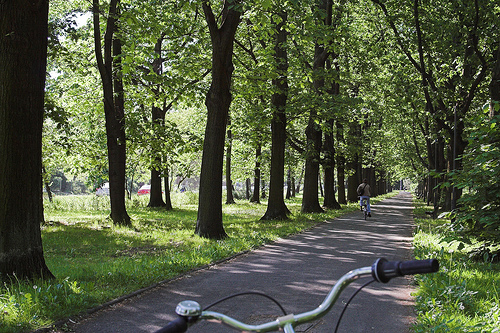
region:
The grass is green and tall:
[78, 212, 174, 284]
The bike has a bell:
[171, 295, 213, 325]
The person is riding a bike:
[351, 177, 396, 246]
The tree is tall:
[151, 6, 253, 261]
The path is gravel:
[316, 212, 381, 326]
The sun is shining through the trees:
[53, 167, 201, 284]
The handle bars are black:
[356, 254, 450, 279]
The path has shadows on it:
[271, 199, 434, 329]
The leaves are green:
[220, 20, 441, 167]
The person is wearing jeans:
[356, 195, 383, 216]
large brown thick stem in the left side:
[0, 2, 52, 283]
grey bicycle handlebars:
[145, 240, 443, 328]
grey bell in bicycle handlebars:
[174, 298, 201, 316]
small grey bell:
[172, 297, 203, 318]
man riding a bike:
[355, 175, 373, 209]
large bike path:
[81, 168, 439, 330]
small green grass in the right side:
[405, 156, 496, 316]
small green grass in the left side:
[1, 150, 351, 320]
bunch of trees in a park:
[1, 7, 398, 275]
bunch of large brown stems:
[1, 7, 398, 278]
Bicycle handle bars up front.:
[156, 252, 442, 332]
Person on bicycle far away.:
[353, 181, 374, 220]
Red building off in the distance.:
[138, 178, 158, 199]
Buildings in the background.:
[81, 173, 271, 200]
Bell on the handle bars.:
[172, 298, 204, 318]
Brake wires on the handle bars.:
[197, 273, 394, 331]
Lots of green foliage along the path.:
[4, 174, 499, 331]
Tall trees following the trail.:
[2, 5, 499, 290]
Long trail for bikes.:
[53, 189, 420, 331]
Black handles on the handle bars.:
[150, 251, 447, 332]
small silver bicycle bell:
[172, 292, 201, 321]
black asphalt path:
[154, 184, 420, 326]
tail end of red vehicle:
[133, 180, 153, 199]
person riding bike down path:
[356, 173, 371, 218]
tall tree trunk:
[191, 31, 235, 243]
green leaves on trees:
[347, 41, 422, 136]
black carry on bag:
[355, 182, 370, 197]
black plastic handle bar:
[367, 250, 439, 288]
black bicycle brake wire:
[202, 283, 297, 321]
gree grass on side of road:
[438, 242, 487, 322]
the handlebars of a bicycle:
[140, 245, 448, 332]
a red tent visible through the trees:
[134, 179, 151, 197]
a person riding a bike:
[352, 173, 375, 224]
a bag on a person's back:
[350, 178, 370, 200]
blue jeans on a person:
[357, 192, 371, 217]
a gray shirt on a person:
[357, 183, 372, 197]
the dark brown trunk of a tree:
[190, 118, 229, 239]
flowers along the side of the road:
[28, 283, 85, 304]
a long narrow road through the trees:
[40, 191, 415, 332]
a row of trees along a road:
[268, 119, 399, 221]